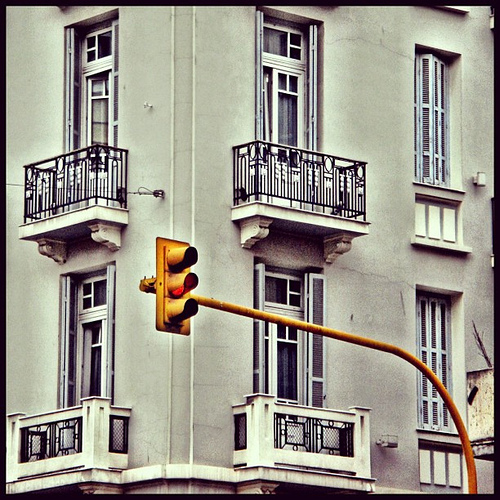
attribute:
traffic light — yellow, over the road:
[142, 232, 486, 495]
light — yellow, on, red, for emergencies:
[167, 272, 190, 298]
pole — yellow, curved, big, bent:
[148, 279, 489, 500]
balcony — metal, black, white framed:
[230, 140, 369, 220]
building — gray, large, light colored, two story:
[6, 7, 491, 494]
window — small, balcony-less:
[411, 44, 458, 187]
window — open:
[261, 17, 314, 65]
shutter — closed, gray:
[413, 48, 435, 183]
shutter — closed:
[431, 53, 449, 188]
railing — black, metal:
[232, 140, 369, 215]